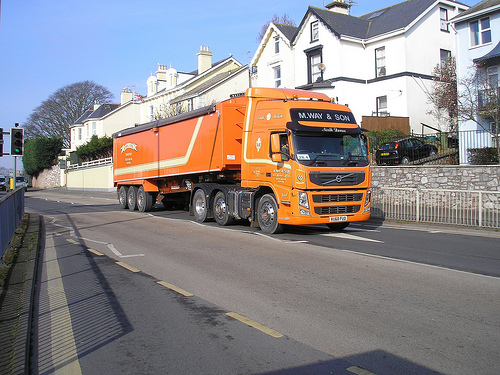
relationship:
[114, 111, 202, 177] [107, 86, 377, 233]
line aside truck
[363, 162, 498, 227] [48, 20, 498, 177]
wall in front of homes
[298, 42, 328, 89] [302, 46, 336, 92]
trim on window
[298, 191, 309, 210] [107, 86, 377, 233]
light on truck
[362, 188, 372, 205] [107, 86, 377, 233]
light on truck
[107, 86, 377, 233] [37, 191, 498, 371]
truck driving on street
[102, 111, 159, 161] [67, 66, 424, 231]
sign on truck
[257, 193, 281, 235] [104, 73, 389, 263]
tire on truck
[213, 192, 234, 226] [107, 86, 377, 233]
tire on truck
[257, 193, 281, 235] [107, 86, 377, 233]
tire on truck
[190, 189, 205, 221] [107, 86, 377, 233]
tire on truck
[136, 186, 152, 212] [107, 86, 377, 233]
tire on truck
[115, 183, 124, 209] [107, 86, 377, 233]
tire on truck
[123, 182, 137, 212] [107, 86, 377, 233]
tire on truck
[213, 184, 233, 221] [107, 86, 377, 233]
tire on truck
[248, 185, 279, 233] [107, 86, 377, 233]
tire on truck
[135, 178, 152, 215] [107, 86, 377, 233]
tire on truck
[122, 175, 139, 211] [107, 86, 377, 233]
tire on truck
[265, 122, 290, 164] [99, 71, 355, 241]
mirror on truck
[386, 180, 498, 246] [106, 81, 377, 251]
truck grill on truck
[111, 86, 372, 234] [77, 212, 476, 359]
truck on road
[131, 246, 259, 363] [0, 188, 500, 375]
lines on road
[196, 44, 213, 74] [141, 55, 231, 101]
chimney on rooftop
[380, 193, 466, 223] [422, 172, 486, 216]
shadow of fence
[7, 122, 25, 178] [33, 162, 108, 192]
streetlight next to fence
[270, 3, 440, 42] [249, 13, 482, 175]
roof of house